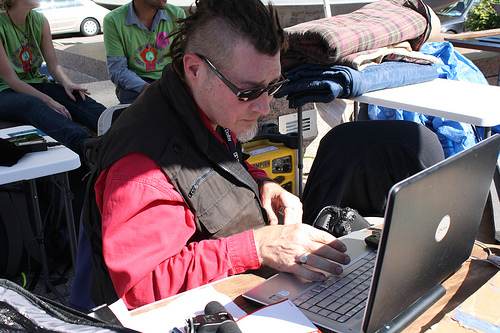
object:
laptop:
[241, 133, 498, 332]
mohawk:
[162, 0, 284, 79]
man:
[69, 0, 352, 318]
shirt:
[93, 128, 261, 309]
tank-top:
[0, 8, 54, 92]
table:
[358, 78, 499, 126]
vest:
[71, 62, 271, 317]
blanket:
[274, 61, 440, 110]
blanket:
[278, 0, 442, 71]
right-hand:
[253, 222, 351, 282]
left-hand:
[258, 179, 304, 223]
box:
[242, 133, 295, 195]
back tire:
[79, 18, 100, 36]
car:
[34, 0, 111, 36]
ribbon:
[18, 47, 33, 73]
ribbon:
[140, 45, 160, 72]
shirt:
[105, 2, 186, 80]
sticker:
[156, 32, 170, 48]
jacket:
[301, 119, 445, 221]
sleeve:
[95, 153, 264, 311]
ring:
[300, 254, 308, 268]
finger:
[288, 268, 326, 281]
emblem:
[431, 213, 450, 243]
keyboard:
[293, 248, 381, 323]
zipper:
[189, 165, 216, 195]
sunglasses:
[237, 78, 290, 101]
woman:
[1, 1, 107, 159]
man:
[104, 0, 188, 104]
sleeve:
[107, 55, 147, 93]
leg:
[293, 105, 304, 199]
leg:
[354, 99, 359, 121]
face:
[209, 41, 281, 141]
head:
[184, 18, 283, 144]